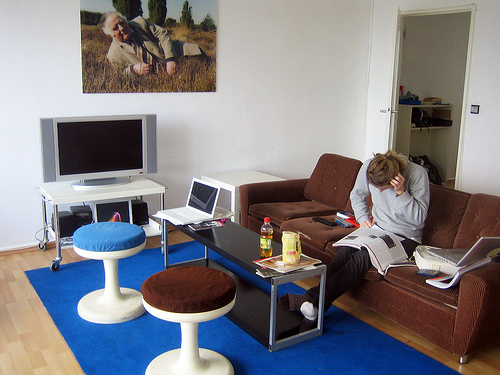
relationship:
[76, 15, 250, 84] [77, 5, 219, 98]
picture on wall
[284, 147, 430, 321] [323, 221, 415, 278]
man reading magazine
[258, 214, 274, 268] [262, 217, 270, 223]
bottle has cap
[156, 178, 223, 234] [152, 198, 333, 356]
laptop on table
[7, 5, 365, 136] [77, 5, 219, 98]
wall has picture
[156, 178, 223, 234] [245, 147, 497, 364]
laptop on couch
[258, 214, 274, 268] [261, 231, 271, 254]
bottle contains drink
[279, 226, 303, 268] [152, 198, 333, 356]
container on table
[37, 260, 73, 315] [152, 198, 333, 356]
rug under table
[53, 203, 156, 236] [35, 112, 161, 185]
speakers under television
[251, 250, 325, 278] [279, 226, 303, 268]
magazines under container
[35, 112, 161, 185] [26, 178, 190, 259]
television on stand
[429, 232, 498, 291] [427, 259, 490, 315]
laptop on top of book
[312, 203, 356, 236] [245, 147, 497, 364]
remotes on couch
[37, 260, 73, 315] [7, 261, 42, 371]
rug on floor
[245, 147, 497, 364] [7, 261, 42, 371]
couch on floor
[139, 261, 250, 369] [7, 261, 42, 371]
stool on floor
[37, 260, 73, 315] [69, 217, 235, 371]
rug under stools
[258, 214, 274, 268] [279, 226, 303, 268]
bottle next to container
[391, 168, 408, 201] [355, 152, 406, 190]
fingers in hair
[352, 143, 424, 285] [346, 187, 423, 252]
man wearing shirt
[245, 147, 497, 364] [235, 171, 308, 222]
sofa has arm